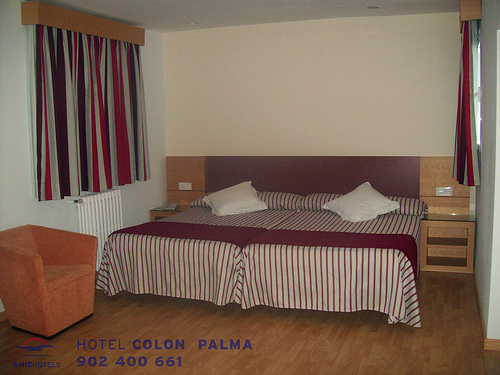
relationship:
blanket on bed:
[101, 217, 423, 283] [98, 172, 429, 334]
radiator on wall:
[74, 186, 127, 282] [0, 0, 182, 279]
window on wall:
[22, 0, 148, 203] [0, 0, 182, 279]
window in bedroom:
[22, 0, 148, 203] [6, 0, 499, 373]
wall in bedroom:
[0, 0, 182, 279] [6, 0, 499, 373]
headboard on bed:
[162, 155, 478, 216] [98, 172, 429, 334]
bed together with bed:
[94, 183, 302, 309] [231, 188, 430, 331]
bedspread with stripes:
[97, 185, 429, 333] [96, 189, 428, 330]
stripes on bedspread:
[96, 189, 428, 330] [97, 185, 429, 333]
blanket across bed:
[101, 217, 423, 283] [94, 183, 302, 309]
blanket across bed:
[101, 217, 423, 283] [231, 188, 430, 331]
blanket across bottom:
[101, 217, 423, 283] [97, 210, 262, 301]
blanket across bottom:
[101, 217, 423, 283] [231, 223, 429, 319]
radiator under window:
[74, 186, 127, 282] [22, 0, 148, 203]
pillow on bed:
[202, 176, 270, 217] [94, 183, 302, 309]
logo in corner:
[12, 332, 64, 372] [2, 269, 111, 371]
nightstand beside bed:
[418, 212, 485, 279] [231, 188, 430, 331]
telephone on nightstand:
[150, 197, 179, 214] [151, 201, 188, 223]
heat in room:
[74, 186, 127, 282] [6, 0, 499, 373]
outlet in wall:
[433, 183, 458, 199] [147, 8, 479, 211]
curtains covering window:
[28, 23, 487, 199] [22, 0, 148, 203]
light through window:
[466, 16, 483, 202] [451, 1, 491, 193]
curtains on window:
[28, 23, 487, 199] [22, 0, 148, 203]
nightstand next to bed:
[151, 201, 188, 223] [98, 172, 429, 334]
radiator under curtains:
[74, 186, 127, 282] [28, 23, 487, 199]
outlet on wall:
[433, 183, 458, 199] [147, 8, 479, 211]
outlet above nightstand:
[433, 183, 458, 199] [418, 212, 485, 279]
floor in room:
[5, 253, 500, 370] [6, 0, 499, 373]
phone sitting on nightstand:
[152, 197, 180, 213] [151, 201, 188, 223]